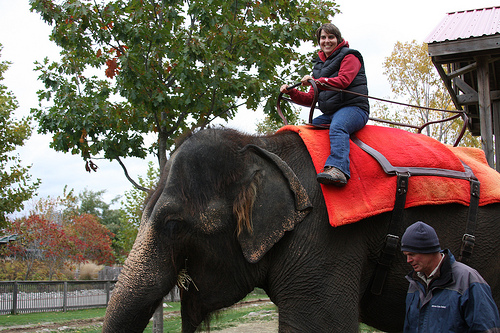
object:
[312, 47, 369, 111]
vest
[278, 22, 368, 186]
woman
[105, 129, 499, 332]
elephant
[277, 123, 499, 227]
carpet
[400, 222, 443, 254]
cap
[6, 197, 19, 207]
leaves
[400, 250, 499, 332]
jacket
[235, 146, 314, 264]
ear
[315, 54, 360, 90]
sleeve